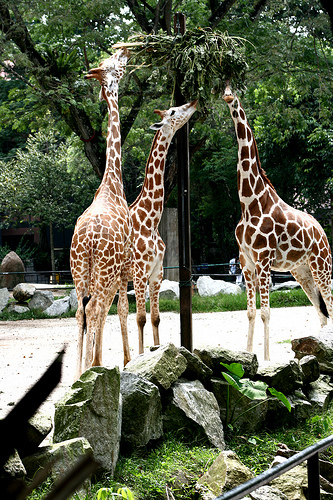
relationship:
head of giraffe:
[155, 101, 198, 130] [108, 100, 194, 350]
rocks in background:
[4, 271, 234, 317] [7, 204, 323, 313]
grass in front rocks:
[110, 293, 245, 310] [17, 274, 233, 302]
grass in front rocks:
[110, 293, 245, 310] [0, 276, 243, 302]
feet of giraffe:
[236, 244, 273, 366] [216, 79, 320, 365]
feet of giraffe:
[234, 250, 273, 362] [216, 79, 320, 365]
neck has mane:
[225, 100, 276, 218] [250, 128, 276, 199]